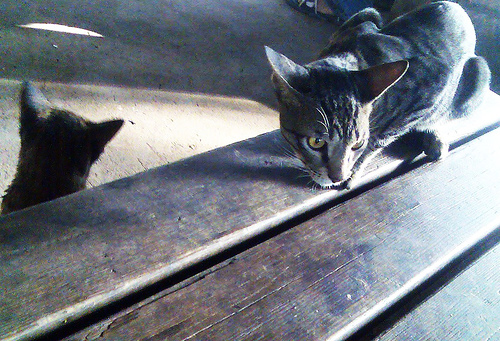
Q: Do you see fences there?
A: No, there are no fences.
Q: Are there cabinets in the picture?
A: No, there are no cabinets.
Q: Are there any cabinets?
A: No, there are no cabinets.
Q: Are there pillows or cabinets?
A: No, there are no cabinets or pillows.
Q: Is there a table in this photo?
A: Yes, there is a table.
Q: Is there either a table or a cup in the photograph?
A: Yes, there is a table.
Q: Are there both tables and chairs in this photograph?
A: No, there is a table but no chairs.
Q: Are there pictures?
A: No, there are no pictures.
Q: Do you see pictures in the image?
A: No, there are no pictures.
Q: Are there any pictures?
A: No, there are no pictures.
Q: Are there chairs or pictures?
A: No, there are no pictures or chairs.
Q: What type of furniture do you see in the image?
A: The furniture is a table.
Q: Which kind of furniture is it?
A: The piece of furniture is a table.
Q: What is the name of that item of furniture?
A: This is a table.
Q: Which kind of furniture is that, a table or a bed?
A: This is a table.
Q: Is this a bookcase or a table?
A: This is a table.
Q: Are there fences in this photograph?
A: No, there are no fences.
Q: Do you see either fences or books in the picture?
A: No, there are no fences or books.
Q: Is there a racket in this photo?
A: No, there are no rackets.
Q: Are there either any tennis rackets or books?
A: No, there are no tennis rackets or books.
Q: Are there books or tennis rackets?
A: No, there are no tennis rackets or books.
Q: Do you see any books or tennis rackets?
A: No, there are no tennis rackets or books.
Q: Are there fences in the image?
A: No, there are no fences.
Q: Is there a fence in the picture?
A: No, there are no fences.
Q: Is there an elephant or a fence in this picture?
A: No, there are no fences or elephants.